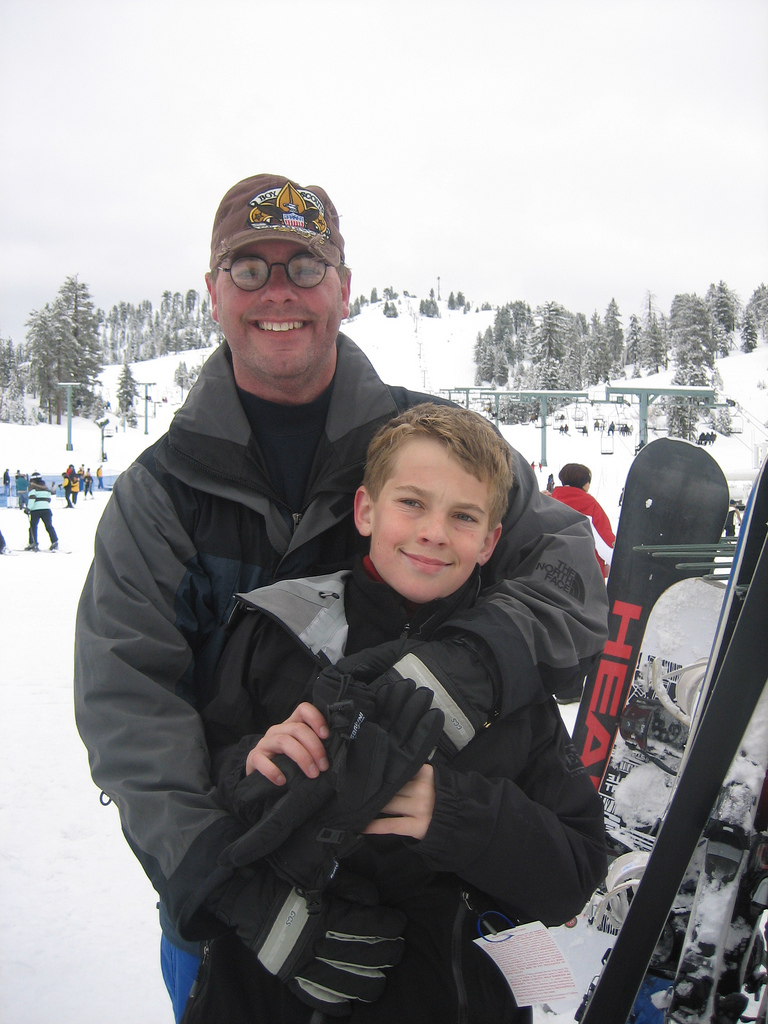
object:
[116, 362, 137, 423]
tree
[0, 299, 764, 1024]
field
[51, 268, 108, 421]
tree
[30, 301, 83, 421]
tree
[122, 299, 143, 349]
tree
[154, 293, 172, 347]
tree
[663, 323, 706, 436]
tree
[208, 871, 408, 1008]
hand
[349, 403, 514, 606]
head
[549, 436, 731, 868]
board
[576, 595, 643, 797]
writing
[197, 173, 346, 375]
head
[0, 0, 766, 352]
sky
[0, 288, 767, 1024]
land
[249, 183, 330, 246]
design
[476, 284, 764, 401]
trees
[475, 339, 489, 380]
snow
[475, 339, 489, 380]
tree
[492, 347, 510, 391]
tree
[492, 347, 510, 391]
snow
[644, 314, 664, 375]
snow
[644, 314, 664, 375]
tree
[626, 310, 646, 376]
tree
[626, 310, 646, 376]
snow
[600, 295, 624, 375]
snow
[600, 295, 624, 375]
tree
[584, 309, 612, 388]
tree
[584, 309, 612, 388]
snow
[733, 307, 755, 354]
snow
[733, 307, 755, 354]
tree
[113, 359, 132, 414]
tree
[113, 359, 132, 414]
snow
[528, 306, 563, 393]
snow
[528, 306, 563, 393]
tree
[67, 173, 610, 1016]
man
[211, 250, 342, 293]
eyeglasses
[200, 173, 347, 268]
cap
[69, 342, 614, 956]
coat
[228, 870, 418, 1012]
glove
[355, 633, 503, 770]
glove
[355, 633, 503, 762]
hand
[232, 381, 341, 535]
shirt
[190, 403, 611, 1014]
boy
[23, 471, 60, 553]
person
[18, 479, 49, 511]
coat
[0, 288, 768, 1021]
ski slope